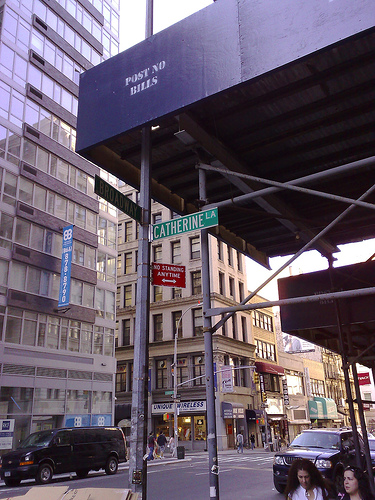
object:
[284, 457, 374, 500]
couple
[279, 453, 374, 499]
sidewalk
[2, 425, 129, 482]
van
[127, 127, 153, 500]
pole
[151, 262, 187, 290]
sign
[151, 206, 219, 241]
street sign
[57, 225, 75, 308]
sign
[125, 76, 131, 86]
letters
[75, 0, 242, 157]
banner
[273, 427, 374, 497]
truck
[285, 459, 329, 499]
woman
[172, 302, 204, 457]
light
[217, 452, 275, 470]
paint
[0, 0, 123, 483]
building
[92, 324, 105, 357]
windows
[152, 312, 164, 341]
windows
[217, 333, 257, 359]
overhang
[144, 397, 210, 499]
street corner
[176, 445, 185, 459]
trash can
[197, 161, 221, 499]
poles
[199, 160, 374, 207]
scaffolding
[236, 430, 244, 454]
pedestrian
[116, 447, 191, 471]
sidewalk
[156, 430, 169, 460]
pedestrians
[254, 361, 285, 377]
awning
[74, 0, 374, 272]
overhag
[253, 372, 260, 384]
traffic light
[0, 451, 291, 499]
street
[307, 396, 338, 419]
overhang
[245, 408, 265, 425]
awning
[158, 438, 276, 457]
sidewalk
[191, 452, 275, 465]
crosswalk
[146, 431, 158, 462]
people